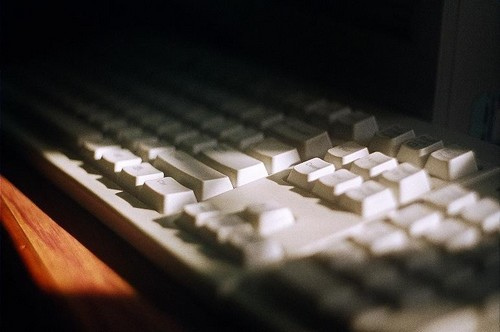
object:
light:
[0, 144, 499, 295]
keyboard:
[0, 44, 499, 332]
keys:
[128, 138, 175, 160]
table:
[0, 0, 499, 331]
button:
[200, 146, 271, 186]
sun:
[0, 174, 134, 298]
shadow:
[0, 230, 499, 332]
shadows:
[421, 146, 478, 180]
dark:
[0, 0, 499, 172]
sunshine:
[307, 280, 360, 313]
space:
[38, 106, 105, 153]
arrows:
[217, 215, 234, 226]